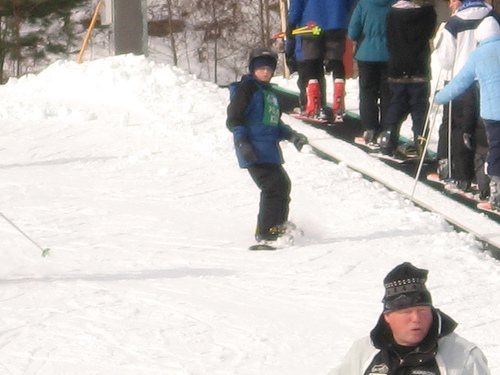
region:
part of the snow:
[406, 220, 423, 232]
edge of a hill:
[170, 258, 205, 313]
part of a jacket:
[364, 347, 369, 349]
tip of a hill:
[108, 115, 128, 145]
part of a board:
[423, 183, 435, 192]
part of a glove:
[243, 153, 251, 163]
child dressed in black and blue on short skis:
[224, 44, 322, 254]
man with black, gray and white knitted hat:
[338, 263, 493, 373]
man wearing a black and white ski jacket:
[334, 264, 491, 374]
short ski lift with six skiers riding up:
[223, 74, 496, 239]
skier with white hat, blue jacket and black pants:
[431, 15, 497, 215]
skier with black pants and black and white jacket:
[427, 0, 495, 197]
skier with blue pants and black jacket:
[370, 2, 438, 172]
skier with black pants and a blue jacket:
[342, 0, 393, 150]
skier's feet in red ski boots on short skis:
[291, 78, 351, 128]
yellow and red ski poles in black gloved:
[274, 21, 325, 40]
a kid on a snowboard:
[219, 42, 307, 251]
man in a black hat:
[321, 258, 492, 373]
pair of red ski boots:
[292, 74, 349, 126]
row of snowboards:
[282, 90, 499, 225]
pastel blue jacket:
[428, 37, 499, 122]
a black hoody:
[382, 0, 435, 82]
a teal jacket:
[348, 1, 388, 63]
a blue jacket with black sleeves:
[223, 73, 293, 168]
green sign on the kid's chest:
[256, 85, 286, 130]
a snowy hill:
[1, 50, 496, 371]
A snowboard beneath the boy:
[255, 224, 300, 248]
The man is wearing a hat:
[381, 262, 433, 308]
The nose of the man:
[411, 312, 421, 322]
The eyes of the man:
[399, 306, 429, 315]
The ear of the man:
[383, 310, 391, 320]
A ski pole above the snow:
[0, 208, 46, 255]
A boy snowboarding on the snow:
[227, 53, 307, 247]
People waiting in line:
[285, 0, 497, 210]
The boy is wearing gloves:
[238, 143, 259, 163]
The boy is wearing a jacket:
[226, 81, 294, 163]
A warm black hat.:
[380, 261, 432, 316]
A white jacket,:
[335, 310, 492, 373]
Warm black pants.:
[249, 162, 290, 240]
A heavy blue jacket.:
[228, 79, 292, 166]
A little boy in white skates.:
[225, 47, 310, 252]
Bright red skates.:
[300, 80, 347, 125]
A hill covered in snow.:
[0, 52, 499, 374]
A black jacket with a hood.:
[385, 0, 436, 81]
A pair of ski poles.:
[272, 22, 324, 43]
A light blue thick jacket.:
[432, 41, 497, 123]